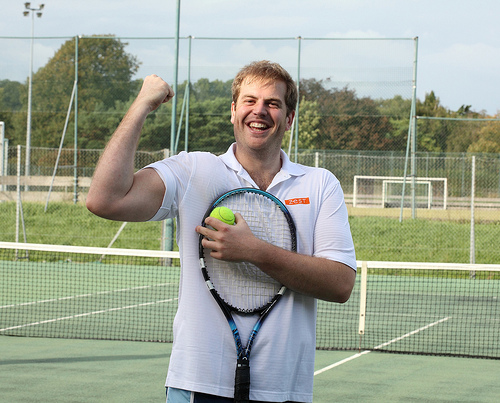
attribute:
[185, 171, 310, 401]
racket — tennis 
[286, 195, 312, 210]
logo — orange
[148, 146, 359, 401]
shirt — polo, white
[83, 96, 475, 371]
field — sport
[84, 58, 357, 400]
player — tennis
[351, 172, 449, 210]
goal — soccer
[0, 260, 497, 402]
court — tennis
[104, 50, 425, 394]
man — tennis playing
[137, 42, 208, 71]
clouds — white, blue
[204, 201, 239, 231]
ball — tennis 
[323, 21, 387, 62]
clouds — white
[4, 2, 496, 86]
sky — blue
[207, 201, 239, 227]
tennis ball — bright yellow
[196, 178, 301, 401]
racket — blue, white, black, tennis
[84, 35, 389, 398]
man — smiling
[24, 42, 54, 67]
clouds — white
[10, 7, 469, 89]
sky — blue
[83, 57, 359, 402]
man — smiling, happy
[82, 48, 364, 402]
male — tennis player